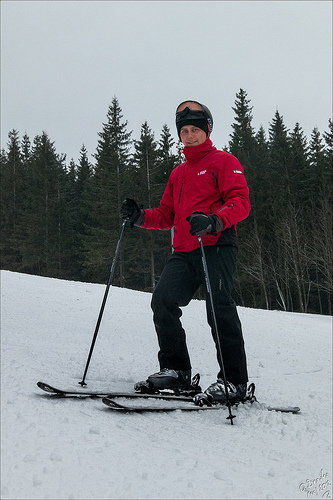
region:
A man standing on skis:
[128, 99, 250, 404]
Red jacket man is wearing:
[139, 140, 251, 251]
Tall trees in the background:
[1, 88, 331, 313]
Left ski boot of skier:
[192, 381, 246, 403]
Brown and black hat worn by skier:
[174, 99, 212, 139]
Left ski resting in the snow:
[99, 394, 300, 413]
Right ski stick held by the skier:
[78, 218, 127, 387]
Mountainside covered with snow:
[0, 268, 331, 496]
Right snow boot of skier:
[133, 371, 191, 391]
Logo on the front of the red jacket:
[196, 166, 209, 176]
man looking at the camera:
[103, 95, 266, 404]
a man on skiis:
[109, 94, 260, 417]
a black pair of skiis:
[30, 375, 273, 420]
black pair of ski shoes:
[124, 362, 257, 410]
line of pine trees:
[0, 87, 330, 318]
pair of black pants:
[148, 232, 256, 384]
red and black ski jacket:
[142, 133, 255, 253]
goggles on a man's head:
[174, 99, 205, 116]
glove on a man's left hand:
[184, 209, 217, 240]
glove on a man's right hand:
[115, 194, 148, 227]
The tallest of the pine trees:
[226, 87, 284, 305]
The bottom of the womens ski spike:
[225, 413, 239, 429]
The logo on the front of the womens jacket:
[195, 170, 204, 179]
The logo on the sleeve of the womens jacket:
[233, 169, 241, 174]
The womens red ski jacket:
[138, 145, 250, 252]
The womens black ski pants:
[151, 248, 249, 384]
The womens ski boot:
[135, 366, 197, 391]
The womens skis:
[42, 380, 299, 417]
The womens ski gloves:
[121, 201, 140, 223]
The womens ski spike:
[189, 226, 235, 428]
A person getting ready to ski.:
[27, 86, 308, 474]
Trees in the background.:
[11, 33, 324, 303]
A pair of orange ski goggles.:
[172, 101, 211, 122]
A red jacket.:
[130, 142, 253, 251]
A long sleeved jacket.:
[133, 139, 252, 249]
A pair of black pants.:
[144, 238, 250, 377]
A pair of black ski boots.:
[138, 363, 258, 403]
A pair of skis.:
[41, 363, 302, 426]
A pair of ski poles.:
[74, 200, 243, 424]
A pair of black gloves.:
[112, 187, 228, 238]